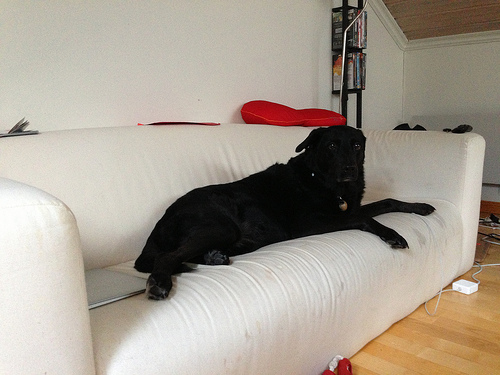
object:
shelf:
[329, 88, 365, 95]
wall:
[0, 3, 403, 136]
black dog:
[130, 124, 438, 302]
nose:
[343, 164, 360, 174]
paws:
[377, 232, 410, 252]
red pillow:
[238, 98, 348, 127]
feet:
[144, 272, 176, 300]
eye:
[326, 139, 345, 154]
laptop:
[79, 269, 151, 311]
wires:
[469, 258, 487, 285]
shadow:
[409, 107, 499, 204]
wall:
[402, 42, 500, 186]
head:
[292, 123, 365, 190]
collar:
[294, 159, 368, 210]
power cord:
[420, 283, 457, 316]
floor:
[334, 224, 499, 374]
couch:
[0, 122, 487, 374]